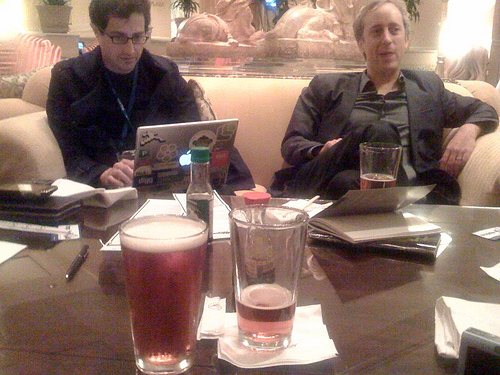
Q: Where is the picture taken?
A: A restaurant.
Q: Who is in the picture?
A: Two men.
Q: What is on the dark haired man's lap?
A: A laptop.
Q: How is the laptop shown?
A: Open.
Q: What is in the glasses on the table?
A: Beer.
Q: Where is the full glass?
A: On the left.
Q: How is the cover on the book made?
A: Soft cover.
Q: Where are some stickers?
A: On cover of laptop.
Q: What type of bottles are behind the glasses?
A: Condiment bottles.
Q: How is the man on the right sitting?
A: Legs are crossed.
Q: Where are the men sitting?
A: On a couch.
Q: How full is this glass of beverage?
A: Almost empty.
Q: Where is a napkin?
A: Under the glass.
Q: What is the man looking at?
A: His laptop.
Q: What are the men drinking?
A: Beer.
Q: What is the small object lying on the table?
A: A pen.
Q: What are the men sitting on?
A: Couch.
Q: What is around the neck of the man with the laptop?
A: An ID badge.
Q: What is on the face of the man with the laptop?
A: Eyeglasses.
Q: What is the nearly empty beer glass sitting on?
A: A cocktail napkin.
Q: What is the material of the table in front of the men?
A: Wood.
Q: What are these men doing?
A: Having a casual business meeting.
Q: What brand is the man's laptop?
A: Apple.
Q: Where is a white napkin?
A: Under a glass.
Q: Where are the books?
A: On the table.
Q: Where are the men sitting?
A: On a couch.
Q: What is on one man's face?
A: Eyeglasses.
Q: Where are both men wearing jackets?
A: Over their shirts.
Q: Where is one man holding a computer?
A: On his lap.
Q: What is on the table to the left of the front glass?
A: Pen.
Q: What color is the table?
A: Brown.